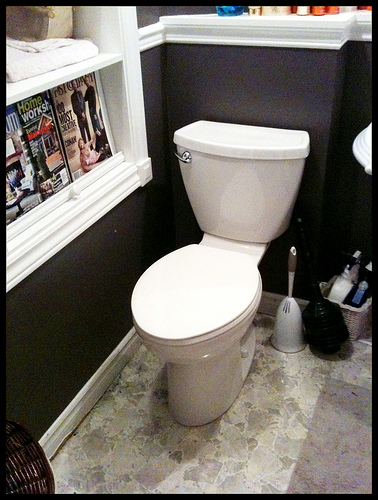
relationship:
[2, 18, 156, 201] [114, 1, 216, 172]
shelf on wall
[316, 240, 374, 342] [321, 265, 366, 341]
bathroom stored in basket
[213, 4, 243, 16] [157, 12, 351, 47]
item lined up ledge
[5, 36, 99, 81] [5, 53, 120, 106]
towel folded shelf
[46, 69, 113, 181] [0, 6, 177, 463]
magazine on wall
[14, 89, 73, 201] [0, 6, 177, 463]
magazine on wall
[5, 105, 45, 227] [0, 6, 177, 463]
magazine on wall